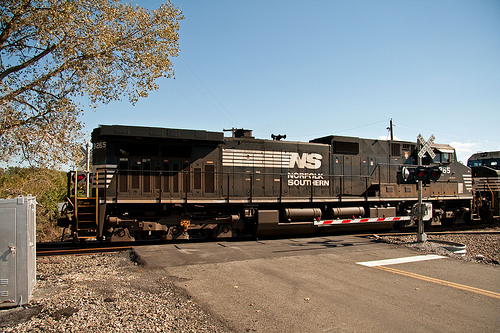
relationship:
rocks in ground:
[36, 254, 170, 331] [34, 233, 496, 331]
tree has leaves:
[1, 1, 185, 174] [38, 8, 180, 103]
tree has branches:
[1, 1, 185, 174] [38, 8, 180, 103]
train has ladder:
[58, 117, 499, 241] [72, 166, 101, 248]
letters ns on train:
[72, 166, 101, 248] [58, 117, 499, 241]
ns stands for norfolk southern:
[287, 150, 326, 172] [284, 168, 333, 189]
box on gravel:
[2, 189, 41, 315] [36, 254, 170, 331]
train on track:
[58, 117, 499, 241] [37, 226, 499, 250]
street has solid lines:
[158, 238, 499, 332] [374, 264, 493, 299]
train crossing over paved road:
[58, 117, 499, 241] [158, 238, 499, 332]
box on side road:
[2, 189, 41, 315] [158, 238, 499, 332]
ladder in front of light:
[72, 166, 101, 248] [69, 164, 86, 186]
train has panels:
[58, 117, 499, 241] [107, 154, 220, 197]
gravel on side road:
[36, 254, 170, 331] [158, 238, 499, 332]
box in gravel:
[2, 189, 41, 315] [36, 254, 170, 331]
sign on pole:
[411, 129, 439, 163] [416, 136, 427, 242]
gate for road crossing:
[305, 209, 430, 247] [302, 130, 445, 253]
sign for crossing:
[411, 129, 439, 163] [305, 209, 430, 247]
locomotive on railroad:
[58, 117, 499, 241] [37, 226, 499, 250]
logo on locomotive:
[217, 146, 336, 189] [58, 117, 499, 241]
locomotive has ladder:
[58, 117, 499, 241] [72, 166, 101, 248]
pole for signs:
[416, 138, 423, 234] [411, 129, 439, 163]